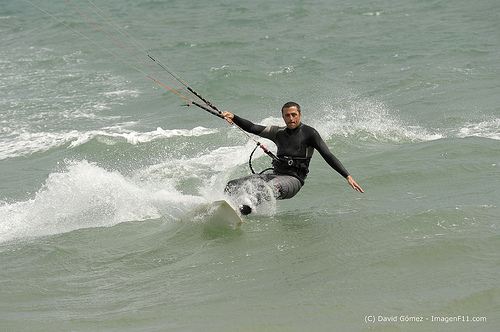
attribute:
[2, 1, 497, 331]
water — green, transparent, clear, not dirt, large, wet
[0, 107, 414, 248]
wave — white, breaking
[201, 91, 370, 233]
man — surfing, parasailing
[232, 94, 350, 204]
wet suit — black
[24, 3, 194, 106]
wire — from kite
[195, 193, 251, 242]
board — white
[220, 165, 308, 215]
bottom — grey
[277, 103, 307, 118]
hair — short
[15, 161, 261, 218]
wake — white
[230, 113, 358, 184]
shirt — black